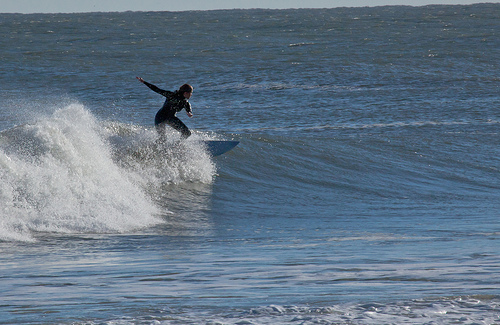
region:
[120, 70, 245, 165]
the person on the surfboard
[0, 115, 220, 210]
the wave in the ocean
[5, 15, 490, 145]
the ocean is calm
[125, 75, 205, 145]
the person wearing a wet suit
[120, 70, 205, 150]
the person is wet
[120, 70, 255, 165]
the person is surfing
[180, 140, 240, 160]
the surfboard is blue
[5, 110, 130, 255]
the wave is crashing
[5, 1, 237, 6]
the sky is blue and clear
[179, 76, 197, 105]
the head of the person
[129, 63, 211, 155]
This woman is surfing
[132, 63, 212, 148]
This woman is a surfer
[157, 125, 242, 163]
This is a surfboard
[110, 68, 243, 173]
Surfer is riding the wave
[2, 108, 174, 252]
The wave is crashing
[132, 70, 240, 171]
Surfer wearing black body suit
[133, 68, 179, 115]
Surfer has her arm out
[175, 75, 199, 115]
Surfer is looking to the side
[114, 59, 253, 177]
Woman is surfing in ocean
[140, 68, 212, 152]
surfer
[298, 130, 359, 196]
blue and white ocean waves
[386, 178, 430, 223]
blue and white ocean waves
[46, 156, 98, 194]
blue and white ocean waves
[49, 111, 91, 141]
blue and white ocean waves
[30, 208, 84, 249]
blue and white ocean waves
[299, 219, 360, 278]
blue and white ocean waves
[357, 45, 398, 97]
blue and white ocean waves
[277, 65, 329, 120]
blue and white ocean waves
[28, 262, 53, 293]
Small ripples in the water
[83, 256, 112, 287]
Small ripples in the water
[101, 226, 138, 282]
Small ripples in the water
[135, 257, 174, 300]
Small ripples in the water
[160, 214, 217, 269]
Small ripples in the water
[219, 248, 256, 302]
Small ripples in the water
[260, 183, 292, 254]
Small ripples in the water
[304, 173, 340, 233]
Small ripples in the water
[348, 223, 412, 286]
Small ripples in the water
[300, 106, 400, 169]
Small ripples in the water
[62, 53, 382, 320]
a body of water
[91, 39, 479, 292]
a body of blue water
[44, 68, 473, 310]
a body of wateer that is blue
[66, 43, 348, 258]
a body of water that is wavy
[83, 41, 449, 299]
a body of wavy water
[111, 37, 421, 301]
a body of blue water with waves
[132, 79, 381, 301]
a woman on a surfboard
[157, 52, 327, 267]
a surfer riding a wave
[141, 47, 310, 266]
a woman on a wave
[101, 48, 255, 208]
a surfer wearing a wetsuit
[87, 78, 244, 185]
a woman on the surfboard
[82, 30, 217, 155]
a woman is surfing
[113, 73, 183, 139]
a woman wearing a wetsuit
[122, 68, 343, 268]
a woman riding a wave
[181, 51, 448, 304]
a body of blue water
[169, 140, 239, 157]
Surf board on the ocean.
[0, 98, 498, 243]
Surfer on the wave.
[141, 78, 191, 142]
Surfer wearing a wet suit.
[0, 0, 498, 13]
The sky is hazy.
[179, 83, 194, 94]
The surfers hair is wet.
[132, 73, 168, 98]
Surfer has her arm in the air.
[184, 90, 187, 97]
Surfer has a ear.